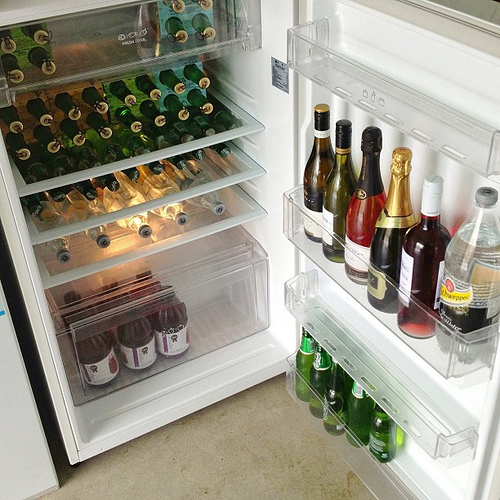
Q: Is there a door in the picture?
A: Yes, there is a door.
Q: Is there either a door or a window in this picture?
A: Yes, there is a door.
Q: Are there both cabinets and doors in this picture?
A: No, there is a door but no cabinets.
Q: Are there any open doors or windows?
A: Yes, there is an open door.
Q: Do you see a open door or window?
A: Yes, there is an open door.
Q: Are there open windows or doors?
A: Yes, there is an open door.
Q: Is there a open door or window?
A: Yes, there is an open door.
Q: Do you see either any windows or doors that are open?
A: Yes, the door is open.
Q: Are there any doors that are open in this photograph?
A: Yes, there is an open door.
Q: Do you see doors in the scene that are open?
A: Yes, there is a door that is open.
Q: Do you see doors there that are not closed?
A: Yes, there is a open door.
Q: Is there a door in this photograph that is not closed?
A: Yes, there is a open door.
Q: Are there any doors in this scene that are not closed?
A: Yes, there is a open door.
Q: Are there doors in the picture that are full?
A: Yes, there is a full door.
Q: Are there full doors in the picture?
A: Yes, there is a full door.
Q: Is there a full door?
A: Yes, there is a full door.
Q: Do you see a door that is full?
A: Yes, there is a door that is full.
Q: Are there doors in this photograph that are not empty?
A: Yes, there is an full door.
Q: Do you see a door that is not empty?
A: Yes, there is an full door.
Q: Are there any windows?
A: No, there are no windows.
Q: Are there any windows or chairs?
A: No, there are no windows or chairs.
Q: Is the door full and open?
A: Yes, the door is full and open.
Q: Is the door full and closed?
A: No, the door is full but open.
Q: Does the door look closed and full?
A: No, the door is full but open.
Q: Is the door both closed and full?
A: No, the door is full but open.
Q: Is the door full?
A: Yes, the door is full.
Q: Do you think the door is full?
A: Yes, the door is full.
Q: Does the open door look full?
A: Yes, the door is full.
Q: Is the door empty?
A: No, the door is full.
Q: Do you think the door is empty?
A: No, the door is full.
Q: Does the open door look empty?
A: No, the door is full.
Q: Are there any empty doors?
A: No, there is a door but it is full.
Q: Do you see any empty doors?
A: No, there is a door but it is full.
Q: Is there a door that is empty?
A: No, there is a door but it is full.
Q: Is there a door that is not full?
A: No, there is a door but it is full.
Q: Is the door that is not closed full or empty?
A: The door is full.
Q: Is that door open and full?
A: Yes, the door is open and full.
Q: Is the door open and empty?
A: No, the door is open but full.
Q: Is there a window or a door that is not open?
A: No, there is a door but it is open.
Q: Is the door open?
A: Yes, the door is open.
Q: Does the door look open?
A: Yes, the door is open.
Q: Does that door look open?
A: Yes, the door is open.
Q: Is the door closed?
A: No, the door is open.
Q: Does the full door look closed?
A: No, the door is open.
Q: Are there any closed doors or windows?
A: No, there is a door but it is open.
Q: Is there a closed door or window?
A: No, there is a door but it is open.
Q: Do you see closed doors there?
A: No, there is a door but it is open.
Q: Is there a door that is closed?
A: No, there is a door but it is open.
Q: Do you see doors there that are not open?
A: No, there is a door but it is open.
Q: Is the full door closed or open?
A: The door is open.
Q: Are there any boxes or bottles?
A: Yes, there is a bottle.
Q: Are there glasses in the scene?
A: No, there are no glasses.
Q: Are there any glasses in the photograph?
A: No, there are no glasses.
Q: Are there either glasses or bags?
A: No, there are no glasses or bags.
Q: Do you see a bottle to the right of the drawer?
A: Yes, there is a bottle to the right of the drawer.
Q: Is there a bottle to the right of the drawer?
A: Yes, there is a bottle to the right of the drawer.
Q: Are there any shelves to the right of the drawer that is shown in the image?
A: No, there is a bottle to the right of the drawer.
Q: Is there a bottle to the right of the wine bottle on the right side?
A: Yes, there is a bottle to the right of the wine bottle.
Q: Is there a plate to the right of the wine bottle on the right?
A: No, there is a bottle to the right of the wine bottle.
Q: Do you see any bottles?
A: Yes, there is a bottle.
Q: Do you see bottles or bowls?
A: Yes, there is a bottle.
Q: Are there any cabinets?
A: No, there are no cabinets.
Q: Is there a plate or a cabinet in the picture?
A: No, there are no cabinets or plates.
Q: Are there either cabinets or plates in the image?
A: No, there are no cabinets or plates.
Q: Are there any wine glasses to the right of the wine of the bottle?
A: No, there is a bottle to the right of the wine.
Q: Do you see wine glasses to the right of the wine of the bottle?
A: No, there is a bottle to the right of the wine.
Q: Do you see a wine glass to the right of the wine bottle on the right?
A: No, there is a bottle to the right of the wine bottle.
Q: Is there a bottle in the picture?
A: Yes, there is a bottle.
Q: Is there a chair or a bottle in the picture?
A: Yes, there is a bottle.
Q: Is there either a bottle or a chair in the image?
A: Yes, there is a bottle.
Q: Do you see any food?
A: No, there is no food.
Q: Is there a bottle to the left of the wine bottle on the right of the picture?
A: Yes, there is a bottle to the left of the wine bottle.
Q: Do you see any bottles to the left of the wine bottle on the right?
A: Yes, there is a bottle to the left of the wine bottle.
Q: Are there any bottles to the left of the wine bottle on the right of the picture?
A: Yes, there is a bottle to the left of the wine bottle.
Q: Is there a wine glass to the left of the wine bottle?
A: No, there is a bottle to the left of the wine bottle.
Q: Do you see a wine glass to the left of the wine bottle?
A: No, there is a bottle to the left of the wine bottle.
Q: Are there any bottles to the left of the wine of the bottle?
A: Yes, there is a bottle to the left of the wine.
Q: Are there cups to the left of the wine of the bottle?
A: No, there is a bottle to the left of the wine.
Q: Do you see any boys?
A: No, there are no boys.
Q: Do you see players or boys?
A: No, there are no boys or players.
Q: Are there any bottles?
A: Yes, there is a bottle.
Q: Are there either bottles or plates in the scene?
A: Yes, there is a bottle.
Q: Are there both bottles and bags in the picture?
A: No, there is a bottle but no bags.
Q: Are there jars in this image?
A: No, there are no jars.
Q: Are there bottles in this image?
A: Yes, there is a bottle.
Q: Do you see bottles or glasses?
A: Yes, there is a bottle.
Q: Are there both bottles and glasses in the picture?
A: No, there is a bottle but no glasses.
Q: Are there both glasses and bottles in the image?
A: No, there is a bottle but no glasses.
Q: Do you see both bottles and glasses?
A: No, there is a bottle but no glasses.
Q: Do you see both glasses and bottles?
A: No, there is a bottle but no glasses.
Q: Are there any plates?
A: No, there are no plates.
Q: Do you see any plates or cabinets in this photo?
A: No, there are no plates or cabinets.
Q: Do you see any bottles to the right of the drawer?
A: Yes, there is a bottle to the right of the drawer.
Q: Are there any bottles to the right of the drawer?
A: Yes, there is a bottle to the right of the drawer.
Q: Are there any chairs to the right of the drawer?
A: No, there is a bottle to the right of the drawer.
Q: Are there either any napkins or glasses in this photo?
A: No, there are no glasses or napkins.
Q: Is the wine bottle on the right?
A: Yes, the wine bottle is on the right of the image.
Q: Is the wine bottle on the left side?
A: No, the wine bottle is on the right of the image.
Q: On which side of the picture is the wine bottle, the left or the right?
A: The wine bottle is on the right of the image.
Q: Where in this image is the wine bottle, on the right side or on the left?
A: The wine bottle is on the right of the image.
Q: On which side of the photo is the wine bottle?
A: The wine bottle is on the right of the image.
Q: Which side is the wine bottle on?
A: The wine bottle is on the right of the image.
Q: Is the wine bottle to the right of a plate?
A: No, the wine bottle is to the right of the bottle.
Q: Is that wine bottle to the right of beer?
A: No, the wine bottle is to the right of the wine.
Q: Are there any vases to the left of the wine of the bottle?
A: No, there is a wine bottle to the left of the wine.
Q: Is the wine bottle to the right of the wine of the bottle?
A: No, the wine bottle is to the left of the wine.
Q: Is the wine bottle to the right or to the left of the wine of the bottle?
A: The wine bottle is to the left of the wine.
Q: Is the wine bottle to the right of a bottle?
A: Yes, the wine bottle is to the right of a bottle.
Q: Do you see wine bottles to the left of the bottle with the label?
A: Yes, there is a wine bottle to the left of the bottle.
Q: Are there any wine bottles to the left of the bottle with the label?
A: Yes, there is a wine bottle to the left of the bottle.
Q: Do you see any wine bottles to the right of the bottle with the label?
A: No, the wine bottle is to the left of the bottle.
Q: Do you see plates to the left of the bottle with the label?
A: No, there is a wine bottle to the left of the bottle.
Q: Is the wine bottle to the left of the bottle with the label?
A: Yes, the wine bottle is to the left of the bottle.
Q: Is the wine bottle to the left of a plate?
A: No, the wine bottle is to the left of the bottle.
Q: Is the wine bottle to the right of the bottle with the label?
A: No, the wine bottle is to the left of the bottle.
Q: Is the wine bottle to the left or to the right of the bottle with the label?
A: The wine bottle is to the left of the bottle.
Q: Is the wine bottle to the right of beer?
A: No, the wine bottle is to the right of the wine.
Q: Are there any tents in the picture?
A: No, there are no tents.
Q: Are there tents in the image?
A: No, there are no tents.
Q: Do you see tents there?
A: No, there are no tents.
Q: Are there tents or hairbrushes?
A: No, there are no tents or hairbrushes.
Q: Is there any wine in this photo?
A: Yes, there is wine.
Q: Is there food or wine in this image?
A: Yes, there is wine.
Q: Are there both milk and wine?
A: No, there is wine but no milk.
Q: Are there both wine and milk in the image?
A: No, there is wine but no milk.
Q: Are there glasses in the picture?
A: No, there are no glasses.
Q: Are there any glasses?
A: No, there are no glasses.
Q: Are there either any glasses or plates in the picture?
A: No, there are no glasses or plates.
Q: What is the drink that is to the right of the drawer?
A: The drink is wine.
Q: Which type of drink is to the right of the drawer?
A: The drink is wine.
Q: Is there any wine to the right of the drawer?
A: Yes, there is wine to the right of the drawer.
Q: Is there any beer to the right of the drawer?
A: No, there is wine to the right of the drawer.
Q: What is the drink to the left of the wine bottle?
A: The drink is wine.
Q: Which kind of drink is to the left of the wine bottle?
A: The drink is wine.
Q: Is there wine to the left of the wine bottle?
A: Yes, there is wine to the left of the wine bottle.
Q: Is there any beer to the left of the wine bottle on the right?
A: No, there is wine to the left of the wine bottle.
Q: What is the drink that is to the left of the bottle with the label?
A: The drink is wine.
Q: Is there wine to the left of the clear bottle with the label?
A: Yes, there is wine to the left of the bottle.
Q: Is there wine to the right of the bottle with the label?
A: No, the wine is to the left of the bottle.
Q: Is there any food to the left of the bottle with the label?
A: No, there is wine to the left of the bottle.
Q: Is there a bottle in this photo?
A: Yes, there is a bottle.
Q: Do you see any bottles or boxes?
A: Yes, there is a bottle.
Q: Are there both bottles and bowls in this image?
A: No, there is a bottle but no bowls.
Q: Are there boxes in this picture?
A: No, there are no boxes.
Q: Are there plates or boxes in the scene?
A: No, there are no boxes or plates.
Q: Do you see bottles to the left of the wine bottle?
A: Yes, there is a bottle to the left of the wine bottle.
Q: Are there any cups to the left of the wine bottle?
A: No, there is a bottle to the left of the wine bottle.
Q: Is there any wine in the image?
A: Yes, there is wine.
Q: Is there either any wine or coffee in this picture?
A: Yes, there is wine.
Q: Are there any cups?
A: No, there are no cups.